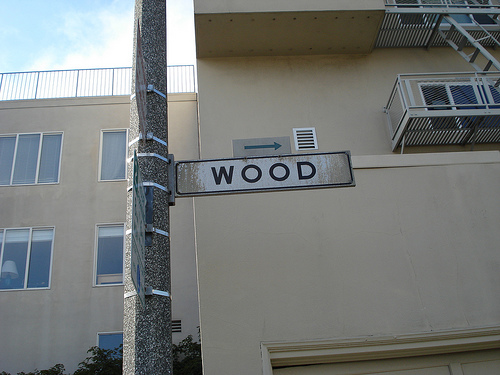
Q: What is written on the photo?
A: Wood.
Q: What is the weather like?
A: Calm.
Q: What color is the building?
A: Cream.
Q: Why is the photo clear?
A: Its during the day.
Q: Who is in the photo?
A: Nobody.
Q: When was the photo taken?
A: During the day.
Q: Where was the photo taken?
A: Wood street.